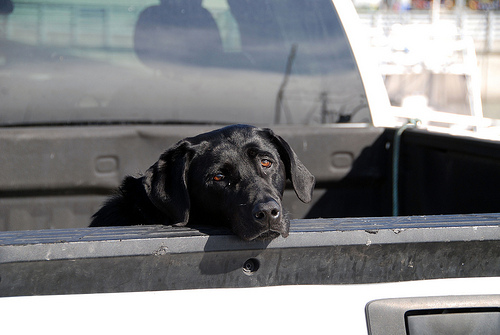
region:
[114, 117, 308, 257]
Dog in the back of truck.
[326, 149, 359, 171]
Knob in the back of truck.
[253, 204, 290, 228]
Black nose on black dog.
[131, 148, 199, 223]
Large ears on a dog.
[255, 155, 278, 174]
Red eyes on a black dog.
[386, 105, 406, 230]
Cord on the back of truck.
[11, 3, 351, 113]
Window in the back of truck.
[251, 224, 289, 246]
A closed dog's mouth.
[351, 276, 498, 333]
Handle to open tailgate.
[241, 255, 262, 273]
Screw in the tailgate.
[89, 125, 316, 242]
a black dog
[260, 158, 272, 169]
a brown eye on a dog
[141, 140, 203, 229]
a black dog ear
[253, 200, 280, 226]
a black dog nose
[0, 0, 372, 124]
the back window of a truck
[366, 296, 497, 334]
the handle of a tailgate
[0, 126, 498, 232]
the bed of a pickup truck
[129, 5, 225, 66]
a head rest in a truck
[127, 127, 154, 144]
a dent in the bed of a truck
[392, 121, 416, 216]
a blue cord hanging in a truck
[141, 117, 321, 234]
dog in the truck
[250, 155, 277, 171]
eye of the dog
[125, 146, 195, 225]
ear of the dog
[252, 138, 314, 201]
ear of the dog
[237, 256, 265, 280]
key hole in the truck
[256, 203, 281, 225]
nose of the dog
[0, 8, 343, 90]
back window of the truck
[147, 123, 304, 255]
head of the dog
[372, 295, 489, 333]
handle of the truck bed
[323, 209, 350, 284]
edge of the truck bed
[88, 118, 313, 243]
Dog in the back of the truck.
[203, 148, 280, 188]
Brown eyes on the dog.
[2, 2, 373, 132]
Back window of the truck.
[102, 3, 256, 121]
Seat in the truck.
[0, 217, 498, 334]
Tailgate on the truck.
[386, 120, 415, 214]
Rope on the truck.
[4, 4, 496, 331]
White truck in the forefront.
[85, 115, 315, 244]
Black hair on the dog.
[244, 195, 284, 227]
black nose on the dog.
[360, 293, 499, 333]
Black handle on the tailgate.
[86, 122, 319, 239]
a sad looking black dog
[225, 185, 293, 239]
a black muzzle of a dog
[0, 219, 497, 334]
the back of a white pickup truck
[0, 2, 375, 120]
the back windshield of a truck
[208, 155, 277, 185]
the sad eyes of a black dog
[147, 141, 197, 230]
a dog's floppy right ear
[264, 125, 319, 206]
a dog's left ear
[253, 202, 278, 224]
a dog's black nose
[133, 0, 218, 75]
the passenger headrest of a truck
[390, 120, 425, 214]
a dog's blue leash